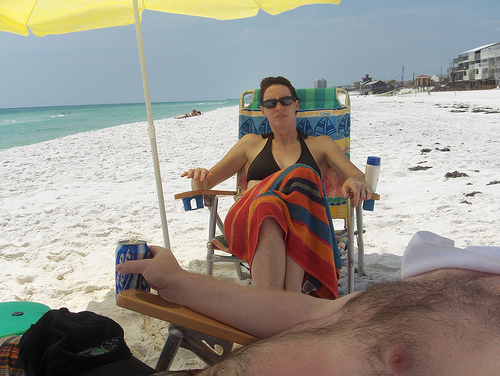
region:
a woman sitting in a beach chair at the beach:
[183, 58, 395, 301]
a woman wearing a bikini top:
[186, 75, 376, 217]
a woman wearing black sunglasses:
[248, 73, 308, 135]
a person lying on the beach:
[171, 101, 206, 133]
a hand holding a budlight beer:
[98, 226, 177, 310]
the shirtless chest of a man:
[180, 258, 498, 373]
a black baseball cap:
[17, 298, 134, 375]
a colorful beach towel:
[219, 149, 341, 285]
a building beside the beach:
[433, 43, 498, 103]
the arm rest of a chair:
[105, 280, 267, 355]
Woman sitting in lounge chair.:
[170, 54, 372, 291]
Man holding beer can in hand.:
[106, 237, 159, 308]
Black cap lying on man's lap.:
[14, 299, 166, 375]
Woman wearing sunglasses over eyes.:
[257, 94, 302, 111]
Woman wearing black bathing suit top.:
[241, 124, 327, 186]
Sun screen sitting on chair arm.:
[358, 154, 389, 213]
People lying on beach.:
[167, 104, 209, 126]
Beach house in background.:
[443, 37, 498, 95]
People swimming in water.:
[53, 104, 80, 120]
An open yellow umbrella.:
[0, 1, 338, 58]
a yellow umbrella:
[3, 0, 349, 27]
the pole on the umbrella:
[125, 2, 180, 247]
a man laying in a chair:
[21, 245, 496, 366]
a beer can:
[110, 236, 151, 296]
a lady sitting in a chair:
[215, 76, 366, 282]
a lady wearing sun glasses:
[221, 76, 361, 291]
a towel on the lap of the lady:
[235, 165, 340, 265]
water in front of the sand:
[20, 96, 150, 151]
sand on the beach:
[25, 145, 145, 235]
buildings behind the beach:
[453, 37, 496, 81]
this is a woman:
[190, 42, 398, 347]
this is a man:
[118, 219, 491, 372]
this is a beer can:
[109, 211, 173, 332]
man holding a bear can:
[112, 222, 499, 372]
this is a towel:
[208, 157, 343, 269]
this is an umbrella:
[16, 5, 337, 75]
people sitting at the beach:
[33, 5, 491, 372]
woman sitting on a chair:
[160, 60, 409, 324]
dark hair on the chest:
[285, 258, 497, 374]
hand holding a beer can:
[104, 225, 169, 295]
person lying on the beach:
[170, 105, 207, 122]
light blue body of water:
[0, 91, 240, 147]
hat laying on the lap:
[10, 305, 152, 374]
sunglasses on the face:
[258, 97, 300, 109]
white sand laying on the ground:
[0, 80, 498, 367]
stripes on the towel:
[213, 156, 355, 288]